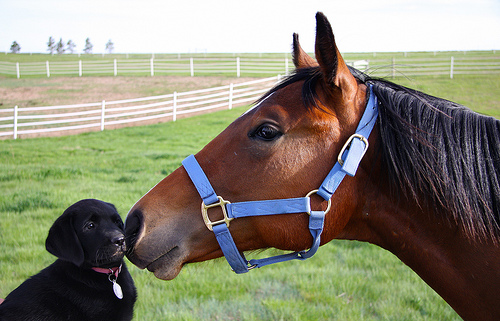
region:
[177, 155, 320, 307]
blue bridle on horse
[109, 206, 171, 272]
horse kissing black puppy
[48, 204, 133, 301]
black puppy with red collar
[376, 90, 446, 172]
horse had a long black mane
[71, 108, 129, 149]
white wooden fence in background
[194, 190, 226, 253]
metal clip on blue bridle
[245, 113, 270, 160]
horse has black eye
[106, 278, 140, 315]
red collar on tag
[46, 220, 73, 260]
dog has floppy ear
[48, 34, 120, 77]
line of scrawny trees in background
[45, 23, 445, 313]
a cute puppy and a horse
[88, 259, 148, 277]
the puppy has a pink collar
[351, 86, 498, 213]
the horse has a black mane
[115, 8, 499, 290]
the horse is brown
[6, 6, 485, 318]
the horse is much larger than the puppy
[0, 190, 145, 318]
the puppy is black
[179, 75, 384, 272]
this is a blue strap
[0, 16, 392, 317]
the puppy is smaller than the horse's head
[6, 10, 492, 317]
these two animals are on a pasture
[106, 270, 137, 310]
the puppy has a small tag on its collar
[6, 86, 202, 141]
white four rail fencing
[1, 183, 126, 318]
cute black dog with a collar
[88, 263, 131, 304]
pink dog collar with a metal tag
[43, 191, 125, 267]
small black dog head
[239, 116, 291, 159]
horse's left eye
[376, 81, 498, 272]
straight and dark horse's mane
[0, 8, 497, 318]
large horse sniffing a small dog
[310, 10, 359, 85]
pointy left horse ear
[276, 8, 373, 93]
pointy horse ears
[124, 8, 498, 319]
brown horse with a dark mane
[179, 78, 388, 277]
a blue halter around the head of a horse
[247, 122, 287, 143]
the left eye of the horse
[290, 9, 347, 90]
the ears of the horse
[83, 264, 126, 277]
a pink collar around the dog's neck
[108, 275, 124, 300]
a dog tag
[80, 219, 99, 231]
the dog's right eye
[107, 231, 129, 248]
the dog's nose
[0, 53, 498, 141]
a white fence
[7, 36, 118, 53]
a stand of trees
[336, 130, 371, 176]
a buckle on the horse's halter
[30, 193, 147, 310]
the dog is black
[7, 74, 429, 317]
the horse is kissing the puppy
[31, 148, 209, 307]
the horse is kissing the puppy